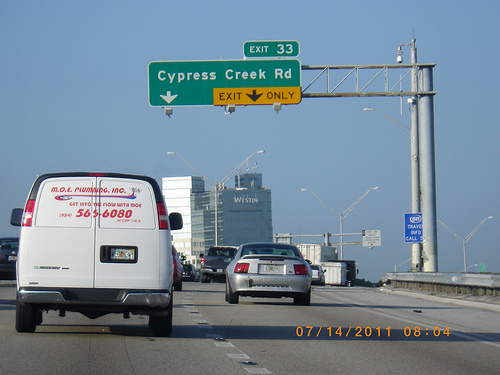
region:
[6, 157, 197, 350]
van driving on street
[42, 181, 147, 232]
sign on a van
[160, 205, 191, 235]
mirror on a van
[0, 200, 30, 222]
mirror on a van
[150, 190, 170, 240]
tail light on a van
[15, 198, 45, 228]
tail light on a van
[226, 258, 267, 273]
tail light on a car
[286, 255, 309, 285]
tail light on a car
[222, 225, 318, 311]
car driving on street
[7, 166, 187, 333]
back end of white van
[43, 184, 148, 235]
red lettering on white van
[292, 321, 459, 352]
time and date stamp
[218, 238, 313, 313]
back end of silver mustang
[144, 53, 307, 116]
green rectangular street sign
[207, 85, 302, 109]
yellow rectangular street sign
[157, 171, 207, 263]
white high rise building in distance on left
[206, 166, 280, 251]
distant high rise building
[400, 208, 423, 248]
blue traffic information sign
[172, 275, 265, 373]
white line lane divider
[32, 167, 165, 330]
white truck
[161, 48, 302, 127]
highway sign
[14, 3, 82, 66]
white clouds in blue sky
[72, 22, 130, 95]
white clouds in blue sky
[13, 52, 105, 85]
white clouds in blue sky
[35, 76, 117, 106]
white clouds in blue sky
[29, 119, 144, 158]
white clouds in blue sky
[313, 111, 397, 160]
white clouds in blue sky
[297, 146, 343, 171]
white clouds in blue sky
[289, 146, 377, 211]
white clouds in blue sky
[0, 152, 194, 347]
the van is white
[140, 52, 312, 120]
the road sign is green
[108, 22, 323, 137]
the road sign is green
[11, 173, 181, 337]
White van on the road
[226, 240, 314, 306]
Silver car on the road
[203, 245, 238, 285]
Black pick up on the road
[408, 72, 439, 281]
Thick gray white poles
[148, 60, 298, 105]
Green and yellow sign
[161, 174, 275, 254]
Tall white building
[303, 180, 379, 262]
Street lights on poles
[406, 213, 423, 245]
Blue sign between poles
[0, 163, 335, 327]
Cars moving on the road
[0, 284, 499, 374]
Gray colored tarmacked road